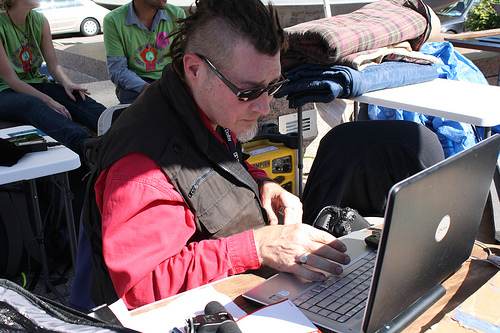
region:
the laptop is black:
[373, 152, 498, 327]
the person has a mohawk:
[157, 0, 290, 162]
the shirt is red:
[92, 151, 289, 330]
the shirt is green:
[99, 3, 204, 118]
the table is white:
[0, 110, 86, 191]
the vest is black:
[130, 88, 297, 274]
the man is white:
[64, 3, 342, 324]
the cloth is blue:
[305, 55, 445, 105]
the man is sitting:
[80, 5, 343, 331]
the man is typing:
[57, 2, 352, 325]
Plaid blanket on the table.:
[289, 12, 423, 48]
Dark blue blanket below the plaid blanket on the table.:
[295, 70, 445, 89]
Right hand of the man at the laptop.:
[255, 222, 340, 282]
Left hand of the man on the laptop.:
[258, 183, 309, 224]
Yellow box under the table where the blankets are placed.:
[249, 150, 302, 187]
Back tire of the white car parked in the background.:
[75, 18, 102, 38]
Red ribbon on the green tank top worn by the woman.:
[17, 50, 37, 68]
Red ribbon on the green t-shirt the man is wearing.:
[140, 42, 162, 69]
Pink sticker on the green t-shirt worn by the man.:
[152, 32, 172, 48]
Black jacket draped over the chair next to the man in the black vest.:
[309, 120, 446, 219]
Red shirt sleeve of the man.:
[97, 163, 267, 286]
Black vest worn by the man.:
[110, 72, 259, 292]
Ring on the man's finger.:
[293, 252, 310, 264]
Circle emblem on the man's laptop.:
[428, 212, 462, 239]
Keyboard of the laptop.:
[284, 245, 378, 318]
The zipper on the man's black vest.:
[177, 163, 217, 202]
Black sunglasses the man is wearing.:
[224, 65, 298, 110]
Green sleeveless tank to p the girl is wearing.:
[2, 17, 58, 84]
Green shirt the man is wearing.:
[107, 13, 184, 73]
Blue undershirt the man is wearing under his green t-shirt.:
[105, 5, 170, 99]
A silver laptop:
[225, 125, 497, 327]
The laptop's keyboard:
[248, 230, 457, 327]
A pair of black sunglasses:
[171, 29, 301, 116]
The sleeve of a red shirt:
[86, 146, 284, 325]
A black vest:
[63, 62, 298, 277]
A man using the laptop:
[73, 5, 485, 330]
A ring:
[289, 251, 323, 273]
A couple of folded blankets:
[256, 6, 456, 113]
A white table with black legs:
[0, 119, 107, 282]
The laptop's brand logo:
[420, 193, 465, 255]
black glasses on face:
[193, 52, 315, 106]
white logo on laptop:
[419, 210, 479, 253]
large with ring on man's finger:
[288, 246, 318, 274]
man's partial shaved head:
[178, 20, 255, 71]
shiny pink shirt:
[78, 137, 254, 297]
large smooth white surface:
[384, 61, 497, 128]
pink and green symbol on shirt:
[129, 40, 165, 74]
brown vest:
[139, 114, 294, 230]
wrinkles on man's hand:
[252, 231, 303, 258]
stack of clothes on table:
[325, 11, 430, 81]